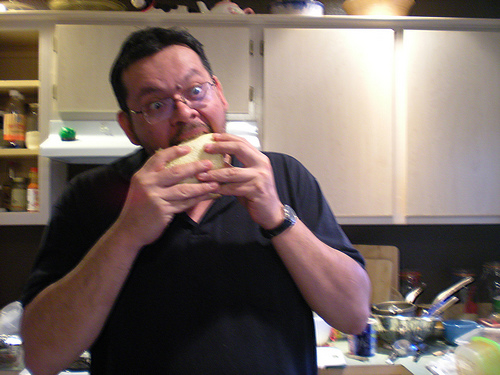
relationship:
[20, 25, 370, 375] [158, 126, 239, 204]
guy eating sandwich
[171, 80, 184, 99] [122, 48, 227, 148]
mole on face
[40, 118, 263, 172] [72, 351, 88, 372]
exhaust fan over stove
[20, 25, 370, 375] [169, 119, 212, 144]
guy has mustache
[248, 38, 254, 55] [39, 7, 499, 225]
screws on cabinets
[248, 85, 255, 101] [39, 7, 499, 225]
screws on cabinets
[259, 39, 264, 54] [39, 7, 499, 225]
screws on cabinets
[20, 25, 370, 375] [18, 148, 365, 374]
guy wearing shirt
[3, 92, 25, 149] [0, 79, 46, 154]
bottle on shelf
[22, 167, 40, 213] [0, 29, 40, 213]
bottle on cupboard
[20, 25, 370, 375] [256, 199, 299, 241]
guy has a watch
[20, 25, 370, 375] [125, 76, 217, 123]
guy has glasses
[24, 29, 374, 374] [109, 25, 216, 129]
guy with black hair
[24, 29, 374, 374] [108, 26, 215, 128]
guy with hair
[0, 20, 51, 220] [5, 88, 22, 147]
cabinet with seasoning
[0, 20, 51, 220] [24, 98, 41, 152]
cabinet with seasoning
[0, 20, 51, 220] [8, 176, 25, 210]
cabinet with seasoning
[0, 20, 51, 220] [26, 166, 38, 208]
cabinet with seasoning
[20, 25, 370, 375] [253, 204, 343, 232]
guy wearing watch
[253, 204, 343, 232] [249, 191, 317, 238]
watch on wrist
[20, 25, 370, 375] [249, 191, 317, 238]
guy with wrist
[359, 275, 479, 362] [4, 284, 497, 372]
dishes on counter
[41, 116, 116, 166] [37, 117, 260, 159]
ball on overhang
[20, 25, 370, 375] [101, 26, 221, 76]
guy has hair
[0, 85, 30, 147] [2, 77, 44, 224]
bottle in cupboard